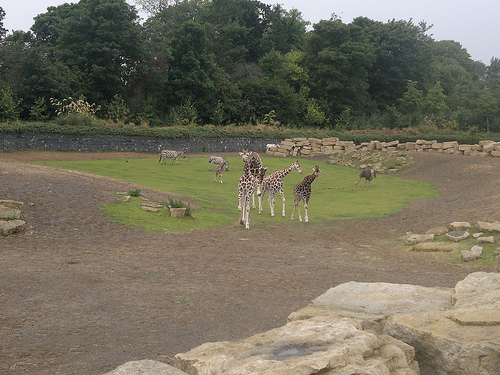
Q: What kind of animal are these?
A: Giraffes.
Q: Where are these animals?
A: A park.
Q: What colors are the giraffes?
A: Brown and white.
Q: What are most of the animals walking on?
A: Grass.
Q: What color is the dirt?
A: Brown.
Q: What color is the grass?
A: Green.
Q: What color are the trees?
A: Green.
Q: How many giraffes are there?
A: Four.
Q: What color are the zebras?
A: Black and white.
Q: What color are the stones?
A: Brown.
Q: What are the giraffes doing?
A: Standing.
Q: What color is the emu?
A: Black and white.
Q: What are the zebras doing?
A: Standing.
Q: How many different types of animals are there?
A: Three.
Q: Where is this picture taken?
A: In a zoo.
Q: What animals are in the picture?
A: Giraffe and zebras.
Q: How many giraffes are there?
A: Five.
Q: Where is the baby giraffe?
A: Near the zebras.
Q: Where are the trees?
A: In the back.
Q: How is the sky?
A: Clear.